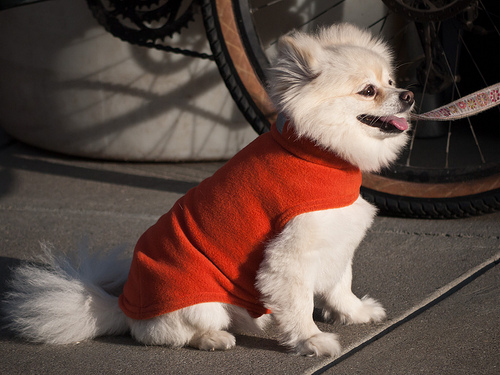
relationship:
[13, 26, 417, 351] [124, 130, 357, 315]
dog in sweater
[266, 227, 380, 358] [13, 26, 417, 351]
legs of dog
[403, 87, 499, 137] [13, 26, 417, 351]
leash going to dog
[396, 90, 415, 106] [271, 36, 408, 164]
nose on dog face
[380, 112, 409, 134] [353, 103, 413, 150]
tongue coming out dog mouth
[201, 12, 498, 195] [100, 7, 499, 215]
tire on bike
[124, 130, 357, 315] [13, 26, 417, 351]
sweater of dog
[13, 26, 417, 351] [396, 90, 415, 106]
dog has nose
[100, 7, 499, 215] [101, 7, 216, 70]
bicycle has chain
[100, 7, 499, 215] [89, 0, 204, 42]
bicycle has sprocket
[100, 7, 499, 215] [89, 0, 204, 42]
bicycle has gear sprocket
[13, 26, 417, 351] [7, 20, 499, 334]
dog looks off distance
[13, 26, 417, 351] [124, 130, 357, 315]
dog wears sweater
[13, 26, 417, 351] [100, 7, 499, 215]
dog sits next to bicycle.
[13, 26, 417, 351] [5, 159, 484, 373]
dog sits on sidewalk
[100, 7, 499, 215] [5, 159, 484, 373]
bicycle parked on sidewalk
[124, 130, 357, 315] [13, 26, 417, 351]
sweater on dog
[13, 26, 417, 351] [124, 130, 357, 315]
dog inside sweater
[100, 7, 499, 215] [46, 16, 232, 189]
bicycle cast shadow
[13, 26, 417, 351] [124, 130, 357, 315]
dog wear sweater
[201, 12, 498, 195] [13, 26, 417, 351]
bicycle wheel behind dog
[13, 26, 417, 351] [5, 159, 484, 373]
dog sitting on sidewalk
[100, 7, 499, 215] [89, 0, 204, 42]
bicycle has gear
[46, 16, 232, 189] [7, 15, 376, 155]
shadow on building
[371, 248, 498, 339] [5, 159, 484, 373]
groove in sidewalk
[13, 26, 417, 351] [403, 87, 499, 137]
dog on leash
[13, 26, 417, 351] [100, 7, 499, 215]
dog standing near bicycle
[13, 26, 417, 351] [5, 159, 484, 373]
dog standing on sidewalk